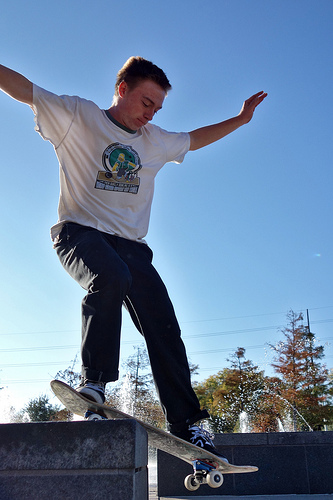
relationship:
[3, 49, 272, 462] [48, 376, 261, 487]
boy on skateboard